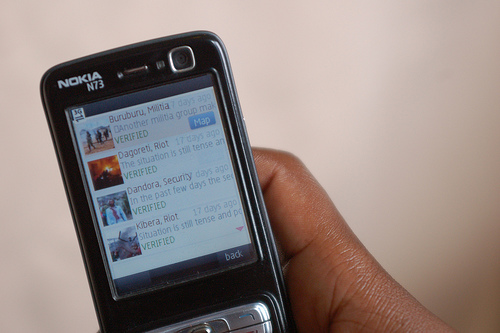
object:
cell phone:
[37, 31, 277, 333]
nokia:
[54, 72, 107, 90]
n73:
[85, 78, 108, 93]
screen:
[63, 84, 252, 296]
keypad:
[164, 302, 277, 332]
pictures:
[101, 222, 146, 264]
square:
[186, 112, 218, 129]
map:
[188, 112, 217, 130]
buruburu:
[109, 109, 145, 121]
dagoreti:
[113, 141, 161, 160]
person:
[248, 134, 465, 332]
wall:
[0, 2, 495, 333]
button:
[225, 304, 268, 325]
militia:
[146, 103, 171, 114]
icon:
[225, 247, 249, 266]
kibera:
[134, 218, 161, 230]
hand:
[254, 147, 444, 332]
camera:
[168, 44, 198, 73]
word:
[122, 163, 162, 179]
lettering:
[195, 117, 210, 127]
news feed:
[94, 82, 228, 268]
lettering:
[222, 251, 246, 260]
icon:
[115, 271, 148, 299]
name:
[107, 101, 173, 123]